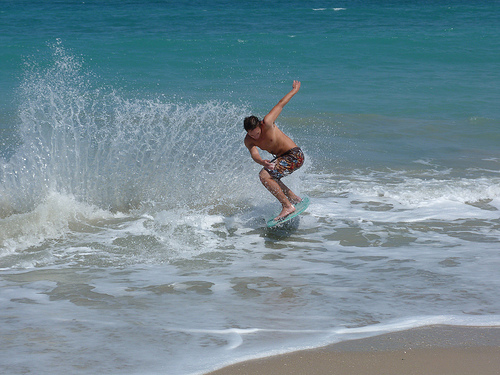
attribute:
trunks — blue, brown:
[260, 141, 305, 183]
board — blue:
[264, 195, 305, 230]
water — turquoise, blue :
[8, 11, 248, 311]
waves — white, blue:
[23, 73, 242, 287]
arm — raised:
[263, 85, 302, 128]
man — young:
[222, 77, 307, 247]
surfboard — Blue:
[261, 195, 311, 233]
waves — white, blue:
[0, 34, 499, 373]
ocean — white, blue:
[1, 1, 496, 371]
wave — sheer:
[0, 56, 336, 259]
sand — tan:
[195, 314, 497, 373]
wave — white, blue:
[2, 154, 495, 253]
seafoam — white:
[2, 162, 499, 373]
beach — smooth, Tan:
[207, 320, 497, 372]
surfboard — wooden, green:
[269, 179, 320, 231]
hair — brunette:
[242, 115, 262, 132]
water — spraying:
[16, 50, 261, 208]